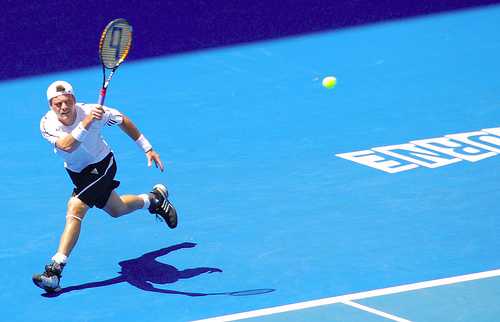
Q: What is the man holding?
A: A racket.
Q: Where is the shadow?
A: On the tennis court.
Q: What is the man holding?
A: A racket.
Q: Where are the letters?
A: On the tennis court.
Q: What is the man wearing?
A: Black shorts.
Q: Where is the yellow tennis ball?
A: Over the court.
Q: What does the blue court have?
A: White lines.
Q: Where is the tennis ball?
A: In the air.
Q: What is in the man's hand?
A: A tennis racket.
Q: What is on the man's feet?
A: Tennis shoes.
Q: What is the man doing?
A: Playing tennis.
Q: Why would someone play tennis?
A: For fun.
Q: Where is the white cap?
A: On the man's head.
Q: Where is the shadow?
A: On the court.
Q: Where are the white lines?
A: On the court.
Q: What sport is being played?
A: Tennis.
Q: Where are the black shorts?
A: On the man.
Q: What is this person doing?
A: Playing tennis.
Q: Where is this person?
A: On a tennis court.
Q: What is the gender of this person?
A: This person is male.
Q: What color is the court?
A: Green.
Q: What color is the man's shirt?
A: White.